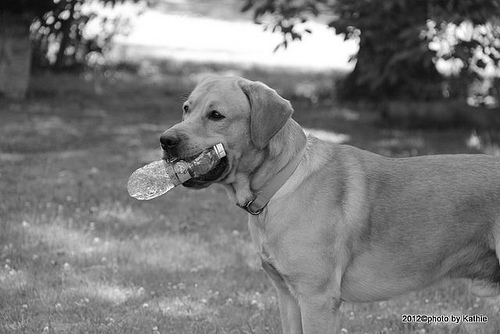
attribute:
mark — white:
[250, 290, 255, 305]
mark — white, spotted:
[251, 294, 261, 304]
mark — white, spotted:
[255, 298, 268, 310]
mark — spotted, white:
[250, 286, 264, 297]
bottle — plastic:
[126, 137, 227, 199]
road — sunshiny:
[31, 0, 498, 77]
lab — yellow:
[159, 74, 498, 332]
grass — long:
[1, 55, 498, 332]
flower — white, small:
[62, 259, 71, 269]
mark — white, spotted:
[142, 297, 155, 307]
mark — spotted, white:
[142, 298, 150, 308]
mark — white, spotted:
[142, 298, 151, 308]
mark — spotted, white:
[140, 298, 152, 308]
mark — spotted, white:
[140, 297, 150, 307]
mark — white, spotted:
[142, 298, 153, 308]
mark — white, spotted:
[155, 298, 164, 305]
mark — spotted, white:
[133, 305, 139, 313]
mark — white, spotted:
[151, 321, 161, 331]